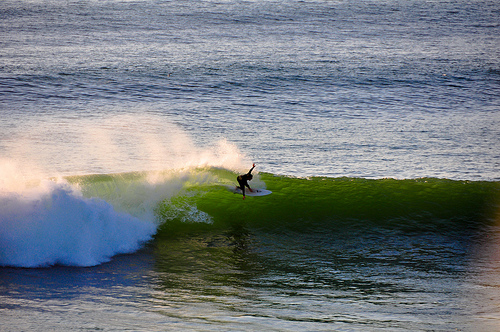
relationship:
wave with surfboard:
[29, 137, 194, 250] [214, 185, 284, 202]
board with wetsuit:
[228, 185, 273, 197] [219, 153, 264, 201]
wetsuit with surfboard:
[232, 161, 268, 192] [218, 177, 262, 201]